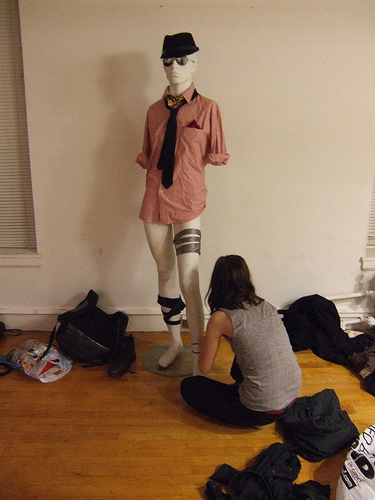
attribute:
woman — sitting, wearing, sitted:
[136, 203, 349, 445]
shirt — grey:
[216, 296, 330, 402]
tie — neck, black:
[144, 70, 199, 198]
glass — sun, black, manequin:
[148, 30, 203, 77]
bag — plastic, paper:
[338, 415, 374, 488]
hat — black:
[153, 23, 207, 64]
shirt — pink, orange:
[117, 92, 235, 232]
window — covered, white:
[5, 68, 30, 232]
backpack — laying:
[55, 268, 168, 397]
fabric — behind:
[235, 403, 337, 488]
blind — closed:
[2, 148, 24, 174]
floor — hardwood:
[59, 384, 182, 498]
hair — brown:
[204, 227, 278, 311]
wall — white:
[5, 35, 154, 187]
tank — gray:
[210, 316, 315, 415]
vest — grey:
[221, 272, 301, 401]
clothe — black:
[274, 386, 364, 489]